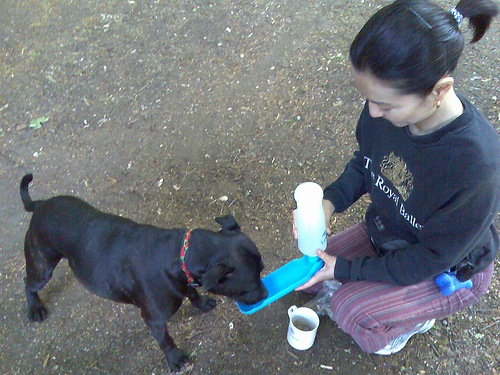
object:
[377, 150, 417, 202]
logo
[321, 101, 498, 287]
shirt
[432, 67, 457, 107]
ear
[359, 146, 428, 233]
design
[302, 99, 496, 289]
sweatshirt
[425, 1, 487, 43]
ponytail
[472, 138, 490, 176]
ground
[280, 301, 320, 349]
cup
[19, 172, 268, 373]
black dog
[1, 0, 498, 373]
ground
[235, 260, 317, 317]
bowl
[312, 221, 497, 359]
striped pants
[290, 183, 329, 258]
blue bottle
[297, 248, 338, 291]
woman's hand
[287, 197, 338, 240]
woman's hand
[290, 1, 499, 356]
woman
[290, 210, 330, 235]
hand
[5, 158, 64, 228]
tail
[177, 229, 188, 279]
red collar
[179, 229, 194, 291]
collar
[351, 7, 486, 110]
woman's hair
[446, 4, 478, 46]
rubber band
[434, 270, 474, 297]
dog bone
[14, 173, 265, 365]
dog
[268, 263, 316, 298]
water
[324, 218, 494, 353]
pants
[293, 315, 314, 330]
water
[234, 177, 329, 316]
water bottle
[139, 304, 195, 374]
leg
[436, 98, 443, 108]
earring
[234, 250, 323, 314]
dish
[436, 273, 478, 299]
object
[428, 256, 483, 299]
pocket